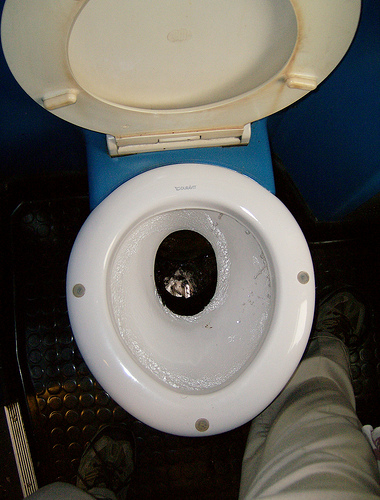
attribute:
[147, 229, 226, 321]
base — color black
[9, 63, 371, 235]
wall — blue, bathroom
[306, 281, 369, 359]
shoe — black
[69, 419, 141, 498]
shoe — black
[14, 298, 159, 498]
mat — black, textured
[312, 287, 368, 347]
shoe — black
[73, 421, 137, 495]
shoe — black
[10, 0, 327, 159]
toilet seat — stained with dirt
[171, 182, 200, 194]
name — manufacturer's brand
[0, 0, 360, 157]
lid — old, up, toilet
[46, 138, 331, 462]
toilet — seat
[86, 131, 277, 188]
support — blue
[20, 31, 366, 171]
toilet seat — sitting up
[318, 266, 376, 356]
boot — brown, of the man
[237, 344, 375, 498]
leg — person's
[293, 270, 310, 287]
dots — gray